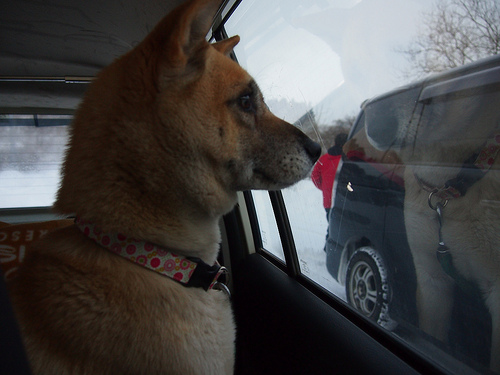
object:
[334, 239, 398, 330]
snow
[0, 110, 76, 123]
antenna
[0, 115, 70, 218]
windshield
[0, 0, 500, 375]
car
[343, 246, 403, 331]
wheel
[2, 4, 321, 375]
dog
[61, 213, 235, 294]
collar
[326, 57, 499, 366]
minivan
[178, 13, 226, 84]
ears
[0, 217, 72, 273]
sign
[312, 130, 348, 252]
man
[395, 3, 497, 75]
tree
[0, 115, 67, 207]
defroster lines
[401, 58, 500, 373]
reflection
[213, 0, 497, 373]
window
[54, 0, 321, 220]
hair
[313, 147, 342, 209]
jacket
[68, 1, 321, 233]
head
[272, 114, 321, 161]
nose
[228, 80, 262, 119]
eye